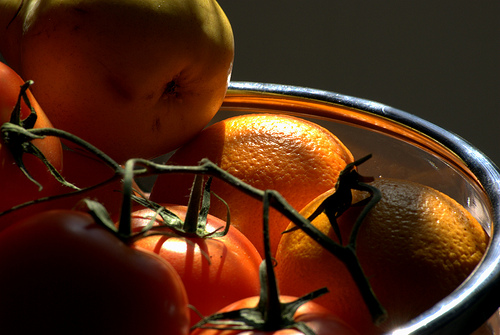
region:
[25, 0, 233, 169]
apple is next to tomato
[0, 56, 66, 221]
tomato is next to apple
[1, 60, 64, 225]
tomato is next to tomato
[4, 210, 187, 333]
tomato is next to tomato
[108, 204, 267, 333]
tomato is next to tomato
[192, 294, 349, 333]
tomato is next to tomato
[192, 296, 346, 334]
tomato is next to orange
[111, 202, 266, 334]
tomato is next to orange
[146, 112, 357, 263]
orange is next to tomato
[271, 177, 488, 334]
orange is next to tomato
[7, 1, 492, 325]
A bowl of produce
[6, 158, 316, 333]
These are tomatoes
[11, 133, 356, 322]
The tomatoes are still on the vine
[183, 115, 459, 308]
These are oranges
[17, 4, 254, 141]
This is a pear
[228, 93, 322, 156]
Light shining on this orange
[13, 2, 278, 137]
The pear is on the top of the bowl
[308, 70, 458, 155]
The rim of the bowl is made of metal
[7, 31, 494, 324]
There are more tomatoes in the bowl than anything else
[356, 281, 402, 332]
There is nothing at the end of this stem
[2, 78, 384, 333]
Vine connecting tomatoes together.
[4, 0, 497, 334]
Oranges and tomatoes in a bowl.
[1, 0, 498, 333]
Oranges and tomatoes in a stainless steel bowl.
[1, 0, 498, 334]
Oranges and tomatoes in a silver bowl.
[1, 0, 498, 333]
Tomatoes and oranges in a bowl.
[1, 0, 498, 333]
Tomatoes and oranges in a silver bowl.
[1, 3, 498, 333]
Tomatoes and oranges in a stainless steel bowl.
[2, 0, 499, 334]
Three oranges in a bowl.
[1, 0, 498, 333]
Four red tomatoes in a bowl.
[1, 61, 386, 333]
Tomatoes still connected by the vine.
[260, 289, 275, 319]
part of a leraf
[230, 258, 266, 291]
part of a shade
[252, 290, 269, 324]
aprt of a tip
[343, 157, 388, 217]
part of a thread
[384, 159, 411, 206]
part gof a food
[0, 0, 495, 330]
oranges apples and tomatoes in a bowl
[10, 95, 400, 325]
stem on the oranges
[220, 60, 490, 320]
the bowl is silver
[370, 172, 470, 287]
holes on the oranges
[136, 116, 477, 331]
light shining on tomatoes and oranges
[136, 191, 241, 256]
green leaves on the stem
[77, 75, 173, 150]
brown color on apple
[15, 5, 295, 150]
the apple is green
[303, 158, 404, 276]
stem laying on orange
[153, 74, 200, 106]
brown stem inside apple